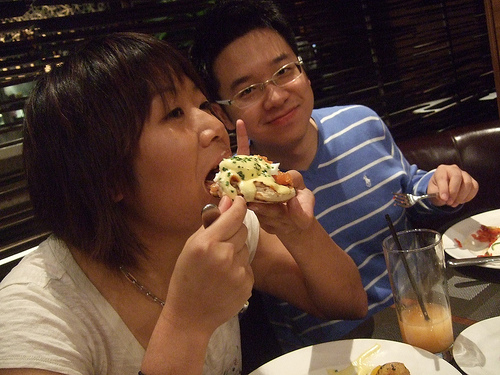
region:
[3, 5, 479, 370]
Couple is eating together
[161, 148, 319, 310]
Person is eating with hands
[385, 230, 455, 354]
Glass has juice in it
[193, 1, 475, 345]
Man is holding fork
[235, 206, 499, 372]
The plates are white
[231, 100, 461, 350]
The shirt is striped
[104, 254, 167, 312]
Woman is wearing a necklace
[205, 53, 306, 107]
Man has eye glasses on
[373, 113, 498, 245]
The booth is burgundy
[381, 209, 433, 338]
Black straw in the glass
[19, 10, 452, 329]
a young asian couple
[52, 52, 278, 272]
an asian woman eating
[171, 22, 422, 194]
an asiam male smiling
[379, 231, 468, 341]
a drinking cup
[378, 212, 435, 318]
a black straw in the cup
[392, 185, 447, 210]
a silver fork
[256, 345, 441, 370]
a large white plate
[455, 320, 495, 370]
a small white plate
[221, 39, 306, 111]
glasses on the man's face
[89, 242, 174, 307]
silver necklace on the woman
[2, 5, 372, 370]
Lady eating with friend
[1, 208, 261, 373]
White top lady is wearing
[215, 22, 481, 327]
Man eating with a friend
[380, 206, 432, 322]
Straw in glass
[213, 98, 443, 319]
Blue and white shirt man is wearing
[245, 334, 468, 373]
White plate in front of young lady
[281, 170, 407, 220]
White strip in blue shirt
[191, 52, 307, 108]
Glasses man is wearing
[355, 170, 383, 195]
Logo on blue and white shirt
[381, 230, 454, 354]
Clear glass with juice in it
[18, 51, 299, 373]
Woman eating some food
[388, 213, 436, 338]
Brown straw in glass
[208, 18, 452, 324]
Man wearing blue and white striped shirt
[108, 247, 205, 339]
Woman wears a necklace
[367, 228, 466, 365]
Glass has a little bit of juice in it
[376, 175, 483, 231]
Man holds a fork in his hand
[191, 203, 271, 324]
woman holds a fork in her hand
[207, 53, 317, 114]
Man wears glasses that are white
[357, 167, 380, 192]
Little horse with rider symbol on shirt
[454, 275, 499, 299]
Reflection of utensil on table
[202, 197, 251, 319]
She holds a utensil.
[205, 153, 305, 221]
She bites the food.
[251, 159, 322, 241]
She holds the food.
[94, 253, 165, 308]
She wears a necklace.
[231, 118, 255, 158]
a mans index finger.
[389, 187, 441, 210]
A silver dinner fork.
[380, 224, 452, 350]
The glass is almost gone.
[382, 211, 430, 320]
The straw in the glass.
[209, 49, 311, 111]
The mans seeing eye glasses.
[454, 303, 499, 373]
A plate on the table.